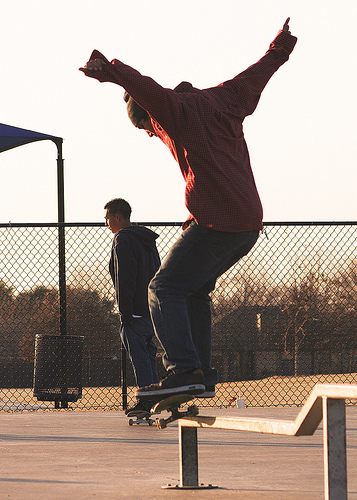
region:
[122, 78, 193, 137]
head of a person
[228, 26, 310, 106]
arm of a person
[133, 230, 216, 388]
leg of a person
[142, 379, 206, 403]
feet of a person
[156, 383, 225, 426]
feet of a person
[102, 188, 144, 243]
head of a person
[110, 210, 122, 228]
ear of a person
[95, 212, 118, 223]
eye of a person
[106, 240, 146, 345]
arm of a person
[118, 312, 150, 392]
leg of a person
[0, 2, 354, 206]
The sky is cloudless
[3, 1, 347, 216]
The sky is summery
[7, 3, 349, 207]
The sky is favorable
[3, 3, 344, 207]
The sky is pleasant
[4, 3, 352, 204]
The sky is radiant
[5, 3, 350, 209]
The sky is clear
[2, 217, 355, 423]
The fence has holes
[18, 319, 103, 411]
The garbage can has holes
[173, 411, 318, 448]
The rail has rust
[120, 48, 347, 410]
Man is on a skateboard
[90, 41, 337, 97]
arms are outstrechted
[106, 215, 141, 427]
person standing on skateboard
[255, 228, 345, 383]
chain linked fence surrounds area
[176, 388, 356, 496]
ramp for the skateboarder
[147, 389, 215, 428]
skateboard coming off ramp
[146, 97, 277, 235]
red jacket on male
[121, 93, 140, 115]
male wearing a cap on head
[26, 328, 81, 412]
black waste bin outside of fence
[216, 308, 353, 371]
building in the back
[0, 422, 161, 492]
pavement is made of clay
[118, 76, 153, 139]
head of a person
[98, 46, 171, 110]
arm of a person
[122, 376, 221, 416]
feet of a person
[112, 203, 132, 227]
ear of a person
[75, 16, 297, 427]
Guy skateboarding on rail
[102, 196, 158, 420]
Guy skateboarding on pavement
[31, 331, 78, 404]
Trash can at park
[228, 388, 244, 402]
Drink with straw on ground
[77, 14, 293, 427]
Skateboarding with arms raised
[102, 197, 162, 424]
Guy with hands in his pockets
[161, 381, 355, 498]
Skateboarding rail at park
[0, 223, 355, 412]
Chain link fence at park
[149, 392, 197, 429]
Skateboard teetering on rail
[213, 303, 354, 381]
House behind chain link fence